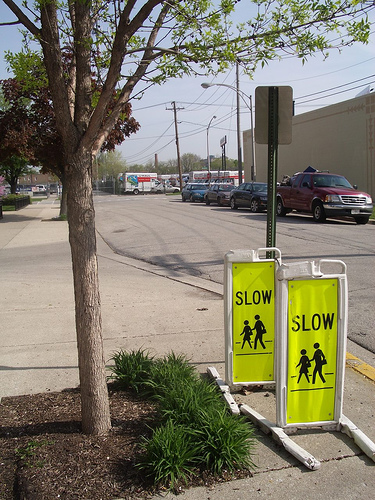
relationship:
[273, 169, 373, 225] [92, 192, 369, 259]
cars parked on street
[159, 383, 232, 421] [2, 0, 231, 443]
bush growing under tree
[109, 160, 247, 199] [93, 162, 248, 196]
uhaul trucks parked in lot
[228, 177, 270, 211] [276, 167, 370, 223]
car behind truck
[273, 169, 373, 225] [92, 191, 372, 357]
cars parked on street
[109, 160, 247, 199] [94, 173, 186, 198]
uhaul trucks behind a fence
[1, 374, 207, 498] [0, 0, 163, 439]
mulch under tree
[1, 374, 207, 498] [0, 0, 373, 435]
mulch around tree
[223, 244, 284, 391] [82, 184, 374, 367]
sign on street